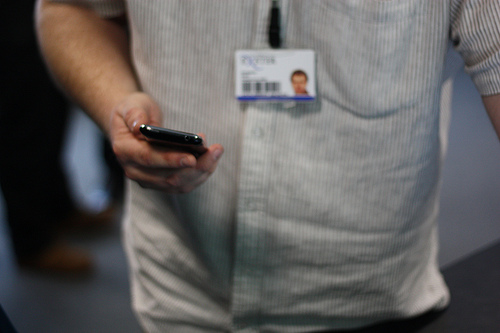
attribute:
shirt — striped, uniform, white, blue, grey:
[104, 1, 499, 330]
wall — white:
[449, 124, 489, 207]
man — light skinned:
[16, 14, 484, 324]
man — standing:
[33, 2, 498, 332]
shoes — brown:
[22, 207, 117, 277]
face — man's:
[290, 70, 309, 98]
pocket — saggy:
[286, 0, 429, 118]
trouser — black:
[7, 124, 82, 257]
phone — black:
[134, 121, 211, 161]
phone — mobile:
[141, 123, 208, 156]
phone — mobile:
[149, 90, 194, 171]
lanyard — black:
[263, 1, 283, 50]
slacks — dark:
[1, 1, 79, 256]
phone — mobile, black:
[143, 125, 208, 165]